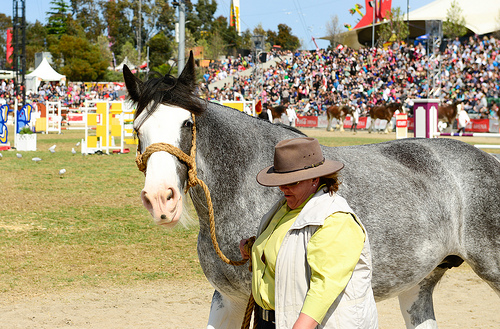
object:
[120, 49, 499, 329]
black horse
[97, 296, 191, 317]
sand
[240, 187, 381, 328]
button down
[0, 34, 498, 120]
audience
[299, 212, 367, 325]
sleeve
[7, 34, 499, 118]
fan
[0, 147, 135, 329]
grass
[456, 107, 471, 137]
people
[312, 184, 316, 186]
earring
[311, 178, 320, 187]
ear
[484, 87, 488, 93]
face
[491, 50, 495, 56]
face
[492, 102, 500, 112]
face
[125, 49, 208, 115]
black hair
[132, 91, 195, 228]
face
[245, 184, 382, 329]
vest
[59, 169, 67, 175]
white pigeon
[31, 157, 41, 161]
white pigeon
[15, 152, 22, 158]
white pigeon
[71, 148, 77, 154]
white pigeon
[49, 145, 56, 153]
white pigeon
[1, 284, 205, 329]
ground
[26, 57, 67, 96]
concessions tent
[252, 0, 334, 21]
sky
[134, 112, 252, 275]
rope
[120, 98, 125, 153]
pole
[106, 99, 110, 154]
pole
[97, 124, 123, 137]
yellow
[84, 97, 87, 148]
pole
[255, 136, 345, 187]
hat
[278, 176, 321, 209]
head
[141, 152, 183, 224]
white snout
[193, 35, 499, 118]
stands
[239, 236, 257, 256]
hand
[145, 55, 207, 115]
mane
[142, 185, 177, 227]
nose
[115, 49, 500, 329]
horse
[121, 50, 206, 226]
head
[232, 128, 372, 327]
woman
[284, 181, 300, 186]
sunglasses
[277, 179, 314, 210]
face